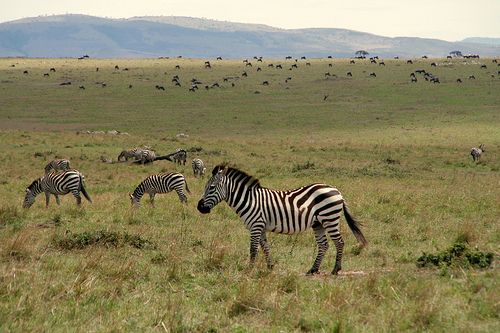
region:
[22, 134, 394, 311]
zebras in the field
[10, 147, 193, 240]
the zebras are eating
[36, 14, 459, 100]
mountains in the distance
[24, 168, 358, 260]
black and white stripes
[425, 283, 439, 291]
part of the grass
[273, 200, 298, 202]
body of a zebra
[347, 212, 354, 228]
tail of a zebra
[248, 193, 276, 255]
leg of a zebra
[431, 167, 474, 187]
part of a plain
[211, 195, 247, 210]
head of a zebra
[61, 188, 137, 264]
part of a bush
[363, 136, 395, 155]
slopes of a mountain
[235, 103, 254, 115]
part of a mountain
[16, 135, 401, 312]
several zebra in the grass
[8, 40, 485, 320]
several animals on a grassy plain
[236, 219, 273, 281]
the front legs of a zebra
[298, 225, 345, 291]
the back legs of a zebra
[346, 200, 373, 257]
the tail of a zebra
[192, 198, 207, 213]
the nose of a zebra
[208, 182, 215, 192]
the eye of a zebra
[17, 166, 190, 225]
two zebras eating grass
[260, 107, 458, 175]
thick green and brown grass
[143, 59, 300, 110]
several animals on a hillside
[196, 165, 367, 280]
a zebra standing in a field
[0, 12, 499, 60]
a distant mountain range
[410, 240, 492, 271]
a short bush in a field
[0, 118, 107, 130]
a patch of dirt in the grassy field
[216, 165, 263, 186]
a black and white mane on a zebra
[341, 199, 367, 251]
a long tail on a zebra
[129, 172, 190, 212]
a zebra eating in a field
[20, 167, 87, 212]
a zebra eating in a field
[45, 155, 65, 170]
a zebra eating in a field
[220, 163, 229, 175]
a zebras ear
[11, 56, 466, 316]
zebras in a field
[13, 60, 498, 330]
zebras walking in a field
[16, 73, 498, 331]
zebras in a green field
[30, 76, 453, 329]
zebras in an area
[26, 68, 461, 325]
zebras walking in an area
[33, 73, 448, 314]
black and white zebras outside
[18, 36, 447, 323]
black and white zebras walking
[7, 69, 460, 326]
black and white zebra walking on grass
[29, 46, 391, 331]
a field of zebras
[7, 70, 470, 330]
a field of black and white zebras